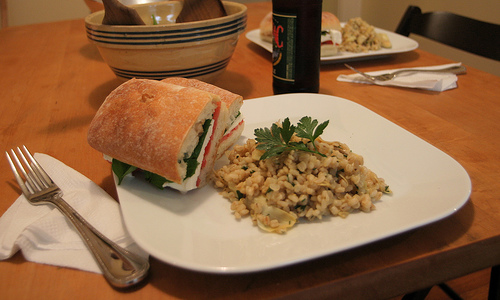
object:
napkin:
[0, 152, 150, 277]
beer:
[272, 0, 323, 95]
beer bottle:
[271, 0, 324, 95]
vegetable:
[253, 115, 330, 160]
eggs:
[209, 121, 393, 235]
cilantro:
[253, 115, 330, 161]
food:
[258, 10, 393, 56]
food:
[85, 76, 393, 235]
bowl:
[84, 0, 249, 86]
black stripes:
[108, 55, 233, 82]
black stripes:
[84, 14, 248, 45]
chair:
[394, 5, 500, 300]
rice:
[339, 17, 392, 53]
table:
[0, 1, 499, 300]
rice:
[207, 119, 391, 234]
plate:
[244, 21, 419, 61]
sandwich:
[86, 76, 245, 195]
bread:
[84, 77, 227, 185]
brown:
[119, 100, 157, 137]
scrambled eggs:
[207, 118, 391, 234]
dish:
[109, 93, 471, 275]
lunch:
[85, 75, 392, 235]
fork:
[344, 63, 467, 81]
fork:
[4, 144, 151, 290]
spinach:
[110, 158, 174, 190]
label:
[271, 12, 296, 81]